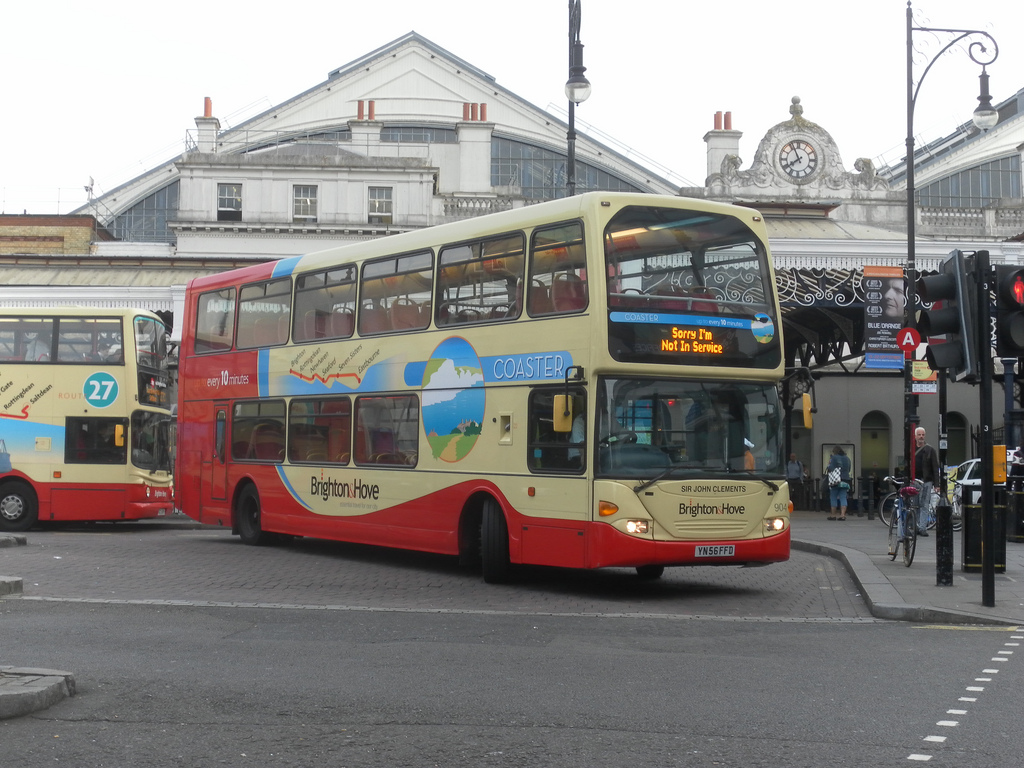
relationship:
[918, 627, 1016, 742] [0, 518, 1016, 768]
lines in roadway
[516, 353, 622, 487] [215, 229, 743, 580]
mirror on bus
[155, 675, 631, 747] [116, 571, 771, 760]
crack on street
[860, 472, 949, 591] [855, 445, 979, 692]
bicycle on sidewalk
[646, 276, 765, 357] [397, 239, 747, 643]
number on bus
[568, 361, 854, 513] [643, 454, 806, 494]
windshield has wiper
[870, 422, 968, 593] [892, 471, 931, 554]
guy wearing jeans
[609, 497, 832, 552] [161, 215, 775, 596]
headlight on bus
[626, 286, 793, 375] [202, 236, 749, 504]
display module on bus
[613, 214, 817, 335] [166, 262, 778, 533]
windshield on bus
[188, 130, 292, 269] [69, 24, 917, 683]
window on building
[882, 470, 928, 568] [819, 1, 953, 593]
bicycle chained to pole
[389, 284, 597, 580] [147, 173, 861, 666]
advertisement on bus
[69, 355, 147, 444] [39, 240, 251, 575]
27 on bus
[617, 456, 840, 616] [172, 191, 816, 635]
plate on bus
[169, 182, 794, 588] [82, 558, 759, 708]
bus on street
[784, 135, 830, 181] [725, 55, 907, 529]
clock in tower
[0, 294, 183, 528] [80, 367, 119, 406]
buses with 27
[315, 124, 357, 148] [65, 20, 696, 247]
window on building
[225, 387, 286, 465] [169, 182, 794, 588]
window on bus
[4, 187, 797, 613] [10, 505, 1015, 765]
buses on street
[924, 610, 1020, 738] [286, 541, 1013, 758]
lines on street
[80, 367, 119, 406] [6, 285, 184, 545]
27 on bus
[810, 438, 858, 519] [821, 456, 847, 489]
person carry bag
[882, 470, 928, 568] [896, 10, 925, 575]
bicycle next pole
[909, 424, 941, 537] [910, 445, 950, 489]
guy wears jacket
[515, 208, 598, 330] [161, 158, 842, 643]
window on bus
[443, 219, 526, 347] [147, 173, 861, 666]
window on bus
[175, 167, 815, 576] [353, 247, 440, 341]
window on bus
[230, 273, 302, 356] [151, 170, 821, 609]
window on bus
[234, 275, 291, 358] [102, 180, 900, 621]
window on bus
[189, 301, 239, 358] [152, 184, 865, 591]
window on bus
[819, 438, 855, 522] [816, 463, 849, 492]
person carrying bag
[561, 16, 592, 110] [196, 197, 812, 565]
light hanging over bus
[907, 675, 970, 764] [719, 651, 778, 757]
line on street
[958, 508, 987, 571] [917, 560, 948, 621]
can on sidewalk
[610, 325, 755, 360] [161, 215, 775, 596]
sign on bus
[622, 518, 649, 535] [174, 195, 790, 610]
headlight of bus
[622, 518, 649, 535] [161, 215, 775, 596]
headlight of bus